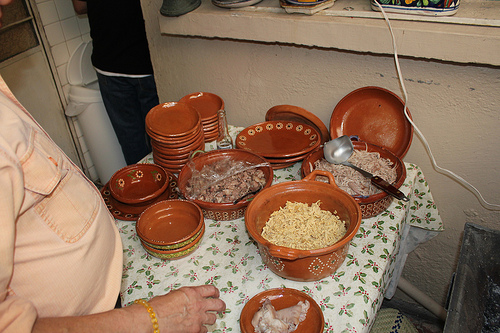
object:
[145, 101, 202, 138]
plates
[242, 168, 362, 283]
bowl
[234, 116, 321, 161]
plate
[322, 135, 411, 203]
spoon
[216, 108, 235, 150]
bottle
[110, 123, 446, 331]
tablecloth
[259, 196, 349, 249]
food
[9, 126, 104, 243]
pocket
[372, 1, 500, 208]
cord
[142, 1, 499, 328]
wall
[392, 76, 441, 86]
marks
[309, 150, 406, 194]
food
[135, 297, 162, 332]
band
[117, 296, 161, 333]
wrist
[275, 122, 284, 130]
design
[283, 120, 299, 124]
edge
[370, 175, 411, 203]
handle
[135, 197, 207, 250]
bowls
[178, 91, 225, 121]
saucers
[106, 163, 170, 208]
bowl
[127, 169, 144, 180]
print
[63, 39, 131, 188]
garbage can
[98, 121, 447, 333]
print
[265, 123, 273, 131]
print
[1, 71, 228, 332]
person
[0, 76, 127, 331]
shirt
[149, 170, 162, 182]
sunflowers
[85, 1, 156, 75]
shirt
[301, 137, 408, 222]
bowl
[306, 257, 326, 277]
design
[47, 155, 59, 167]
hole